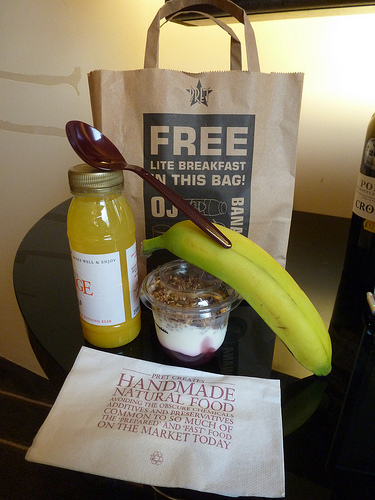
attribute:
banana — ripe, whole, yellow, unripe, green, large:
[141, 218, 332, 377]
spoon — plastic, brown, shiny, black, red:
[67, 121, 233, 248]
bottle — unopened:
[67, 164, 142, 347]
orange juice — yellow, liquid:
[67, 198, 141, 350]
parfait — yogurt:
[138, 259, 245, 361]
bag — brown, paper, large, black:
[88, 1, 304, 287]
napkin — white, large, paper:
[25, 346, 286, 499]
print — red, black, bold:
[95, 367, 236, 452]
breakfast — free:
[68, 166, 332, 376]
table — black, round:
[13, 190, 352, 404]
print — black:
[142, 113, 251, 238]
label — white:
[69, 243, 146, 328]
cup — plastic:
[138, 257, 246, 365]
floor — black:
[1, 381, 154, 499]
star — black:
[185, 79, 213, 106]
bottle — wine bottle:
[343, 114, 374, 257]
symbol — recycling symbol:
[148, 451, 164, 466]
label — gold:
[352, 172, 374, 233]